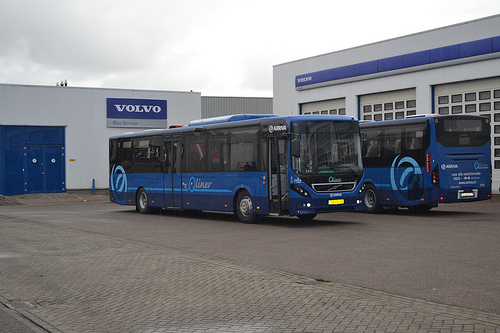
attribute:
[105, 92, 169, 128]
sign — large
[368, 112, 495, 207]
passenger bus — blue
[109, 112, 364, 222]
passenger bus — blue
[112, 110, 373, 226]
bus — passenger, blue,  passenger bus, large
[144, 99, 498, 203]
bus — large , blue 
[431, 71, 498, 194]
door — large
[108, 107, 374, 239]
bus — large 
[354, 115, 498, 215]
bus — blue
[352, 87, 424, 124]
garage door — large